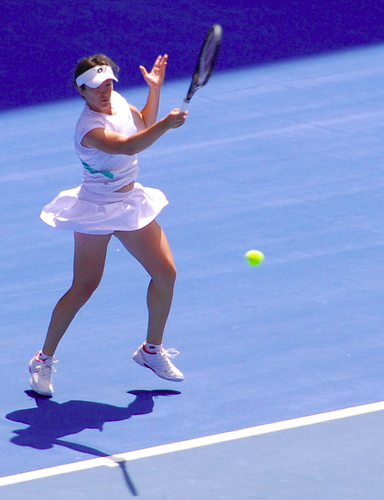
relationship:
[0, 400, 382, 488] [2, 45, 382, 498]
line on ground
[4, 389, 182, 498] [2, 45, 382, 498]
shadow on ground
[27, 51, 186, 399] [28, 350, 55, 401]
woman has a foot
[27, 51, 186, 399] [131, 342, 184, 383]
woman has a foot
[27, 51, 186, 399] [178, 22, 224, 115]
woman holding racket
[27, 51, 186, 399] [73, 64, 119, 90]
woman wearing a hat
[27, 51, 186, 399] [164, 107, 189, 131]
woman has a hand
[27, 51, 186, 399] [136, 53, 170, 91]
woman has a hand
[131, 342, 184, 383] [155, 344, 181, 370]
shoe has laces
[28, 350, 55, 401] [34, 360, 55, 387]
shoe has laces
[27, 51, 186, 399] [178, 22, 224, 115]
woman swinging a racket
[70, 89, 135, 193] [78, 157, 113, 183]
shirt has a stripe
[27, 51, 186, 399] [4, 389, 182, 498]
woman has a shadow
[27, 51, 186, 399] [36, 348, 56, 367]
woman wearing sock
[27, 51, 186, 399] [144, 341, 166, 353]
woman wearing sock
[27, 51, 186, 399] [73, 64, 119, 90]
woman wearing hat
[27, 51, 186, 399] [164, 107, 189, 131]
woman raising her hand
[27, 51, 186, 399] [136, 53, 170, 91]
woman raising her hand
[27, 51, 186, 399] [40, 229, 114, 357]
woman has legs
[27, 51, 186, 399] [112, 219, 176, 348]
woman has legs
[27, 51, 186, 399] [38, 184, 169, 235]
woman wearing a skirt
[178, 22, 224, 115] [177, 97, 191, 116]
racket has a grip